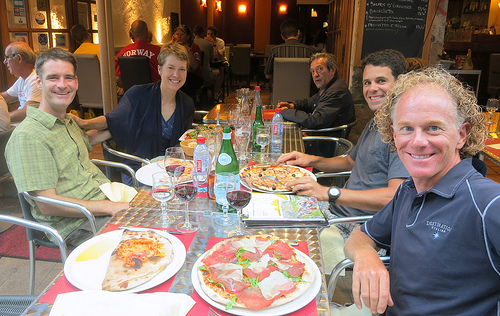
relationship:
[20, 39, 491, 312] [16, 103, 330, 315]
people around a table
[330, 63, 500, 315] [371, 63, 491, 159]
man has curly hair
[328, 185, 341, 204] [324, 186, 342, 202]
watch on a mans wrist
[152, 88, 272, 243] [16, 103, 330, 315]
glasses on table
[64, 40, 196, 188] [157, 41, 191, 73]
woman with short hair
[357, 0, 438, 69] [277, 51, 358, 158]
chalkboard behind man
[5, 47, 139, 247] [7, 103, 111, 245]
man in a green shirt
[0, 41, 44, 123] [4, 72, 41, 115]
man in a white shirt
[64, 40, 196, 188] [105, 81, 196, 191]
woman in a blue shirt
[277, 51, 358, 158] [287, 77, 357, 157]
man wearing a black jacket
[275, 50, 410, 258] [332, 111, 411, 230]
man in a gray shirt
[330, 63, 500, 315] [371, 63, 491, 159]
man with curly hair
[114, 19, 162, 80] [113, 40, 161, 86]
man in a red shirt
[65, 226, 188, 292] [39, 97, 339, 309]
plate on table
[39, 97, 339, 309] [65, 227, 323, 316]
table with drinks and plates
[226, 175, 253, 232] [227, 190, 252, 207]
glass with red wine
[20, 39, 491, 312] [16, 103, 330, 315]
people sitting at a table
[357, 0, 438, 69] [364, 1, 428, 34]
chalkboard with writing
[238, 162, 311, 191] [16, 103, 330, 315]
pizza on table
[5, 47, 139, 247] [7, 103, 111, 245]
man wearing a green shirt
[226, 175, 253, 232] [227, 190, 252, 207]
glass with wine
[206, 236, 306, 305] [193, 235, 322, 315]
food on plate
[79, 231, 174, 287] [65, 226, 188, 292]
food on plate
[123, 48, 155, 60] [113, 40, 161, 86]
norway on shirt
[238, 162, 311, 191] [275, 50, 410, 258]
pizza near man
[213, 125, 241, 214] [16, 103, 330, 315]
bottle on table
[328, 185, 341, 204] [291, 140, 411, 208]
watch on h arm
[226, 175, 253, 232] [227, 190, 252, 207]
glass containing wine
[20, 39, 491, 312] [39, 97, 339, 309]
people at table